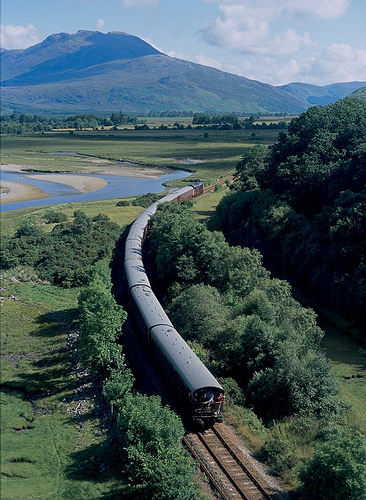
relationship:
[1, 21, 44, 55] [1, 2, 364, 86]
clouds in sky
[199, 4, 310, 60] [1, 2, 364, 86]
clouds in sky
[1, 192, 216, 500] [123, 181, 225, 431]
grass by cars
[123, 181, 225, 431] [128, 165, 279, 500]
cars on tracks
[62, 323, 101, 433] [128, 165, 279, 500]
gravel beside tracks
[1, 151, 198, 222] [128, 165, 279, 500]
pond beside tracks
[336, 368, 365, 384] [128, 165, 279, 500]
hole beside tracks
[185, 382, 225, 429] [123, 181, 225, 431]
front of cars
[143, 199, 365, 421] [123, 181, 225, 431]
trees next to cars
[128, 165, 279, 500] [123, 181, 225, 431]
tracks under cars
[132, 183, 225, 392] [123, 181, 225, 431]
top of cars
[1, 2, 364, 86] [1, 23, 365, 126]
sky above mountainside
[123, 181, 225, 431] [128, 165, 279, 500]
cars down tracks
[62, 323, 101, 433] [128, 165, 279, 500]
gravel near tracks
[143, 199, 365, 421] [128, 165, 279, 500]
trees frame tracks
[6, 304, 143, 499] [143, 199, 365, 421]
shadows by trees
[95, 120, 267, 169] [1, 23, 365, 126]
shadows of mountainside